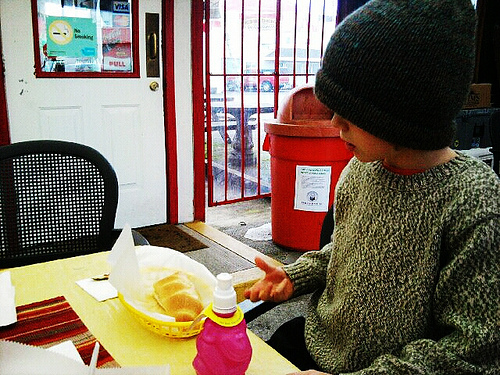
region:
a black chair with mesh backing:
[2, 139, 150, 263]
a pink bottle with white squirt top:
[197, 273, 247, 374]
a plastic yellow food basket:
[115, 280, 205, 339]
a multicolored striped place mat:
[1, 296, 118, 367]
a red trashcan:
[262, 83, 359, 254]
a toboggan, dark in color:
[314, 1, 476, 151]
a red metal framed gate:
[197, 2, 327, 212]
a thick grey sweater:
[283, 153, 496, 373]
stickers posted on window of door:
[37, 2, 136, 73]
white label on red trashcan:
[293, 163, 329, 214]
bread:
[157, 267, 197, 326]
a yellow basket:
[158, 311, 178, 340]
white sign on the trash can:
[299, 166, 326, 210]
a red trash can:
[264, 125, 310, 156]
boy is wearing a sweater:
[338, 195, 461, 320]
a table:
[45, 265, 72, 290]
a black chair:
[13, 150, 105, 230]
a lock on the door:
[148, 75, 165, 92]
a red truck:
[227, 65, 281, 91]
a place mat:
[35, 303, 77, 338]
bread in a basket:
[150, 270, 201, 321]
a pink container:
[198, 295, 261, 367]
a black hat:
[331, 49, 423, 124]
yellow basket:
[152, 313, 174, 333]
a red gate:
[213, 43, 262, 93]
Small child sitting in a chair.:
[313, 0, 495, 372]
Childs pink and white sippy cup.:
[193, 270, 253, 373]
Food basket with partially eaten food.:
[128, 245, 200, 335]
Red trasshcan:
[264, 84, 333, 249]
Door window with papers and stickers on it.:
[34, 0, 136, 77]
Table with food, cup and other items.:
[4, 250, 217, 373]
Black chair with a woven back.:
[1, 140, 118, 262]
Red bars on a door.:
[203, 1, 312, 207]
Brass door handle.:
[144, 12, 161, 77]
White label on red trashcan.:
[294, 168, 329, 211]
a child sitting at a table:
[228, 0, 498, 374]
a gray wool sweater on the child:
[268, 155, 497, 374]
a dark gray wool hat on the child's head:
[311, 0, 487, 157]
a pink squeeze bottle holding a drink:
[188, 266, 254, 373]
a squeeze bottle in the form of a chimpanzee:
[192, 310, 259, 373]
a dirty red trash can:
[261, 75, 353, 257]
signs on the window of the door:
[38, 0, 135, 74]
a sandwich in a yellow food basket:
[107, 222, 222, 339]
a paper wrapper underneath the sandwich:
[108, 219, 223, 324]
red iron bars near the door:
[204, 0, 346, 209]